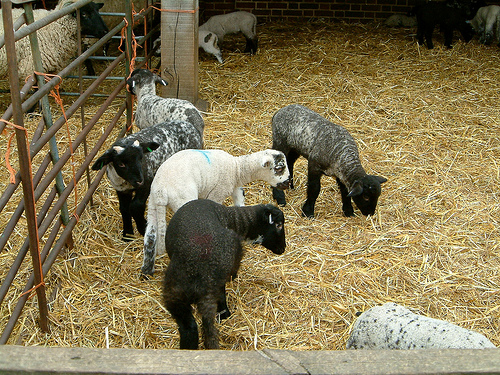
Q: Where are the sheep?
A: In a barn.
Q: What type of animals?
A: Sheep.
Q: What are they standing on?
A: Straw.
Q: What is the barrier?
A: Gates.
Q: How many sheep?
A: Nine.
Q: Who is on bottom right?
A: Black and white spotted sheep.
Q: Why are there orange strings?
A: To connect gates.